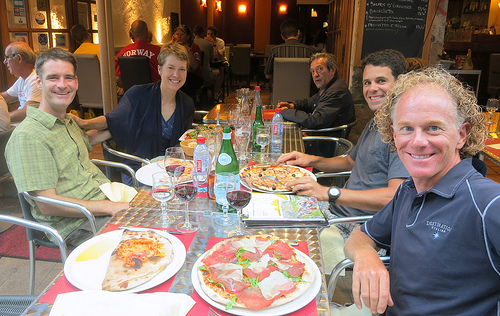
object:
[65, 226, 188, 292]
plate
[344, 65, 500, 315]
man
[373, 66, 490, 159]
hair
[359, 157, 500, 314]
shirt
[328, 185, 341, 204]
watch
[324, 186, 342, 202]
wrist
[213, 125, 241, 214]
bottle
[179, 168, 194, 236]
glasses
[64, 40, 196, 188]
woman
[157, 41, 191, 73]
hair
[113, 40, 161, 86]
shirt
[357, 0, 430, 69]
chalkboard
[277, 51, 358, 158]
man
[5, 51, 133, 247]
man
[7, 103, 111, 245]
shirt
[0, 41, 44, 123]
man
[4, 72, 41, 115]
shirt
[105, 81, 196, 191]
shirt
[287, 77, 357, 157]
jacket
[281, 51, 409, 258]
man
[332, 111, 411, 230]
shirt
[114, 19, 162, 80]
man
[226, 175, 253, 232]
glass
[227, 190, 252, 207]
wine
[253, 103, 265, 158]
bottles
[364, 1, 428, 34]
writing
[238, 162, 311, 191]
pizza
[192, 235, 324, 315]
mat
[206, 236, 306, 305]
food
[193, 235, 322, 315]
plate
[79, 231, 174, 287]
food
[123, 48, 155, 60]
norway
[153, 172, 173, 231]
glasses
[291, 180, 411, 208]
arm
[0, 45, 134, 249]
people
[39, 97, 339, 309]
table